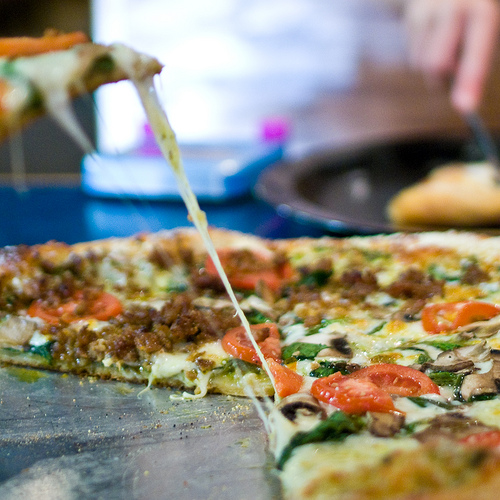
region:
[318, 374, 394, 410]
tomato on pizza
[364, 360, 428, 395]
red tomaoto as topping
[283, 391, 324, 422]
mushroom on the pizza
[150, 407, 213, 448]
pizza crumbs on pan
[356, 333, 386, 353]
cheese on the pizza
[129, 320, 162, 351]
hamburger on the pizza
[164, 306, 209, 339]
meat on pizza as topping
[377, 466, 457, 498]
crust of the pizza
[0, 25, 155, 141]
slice of the pizza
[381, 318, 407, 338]
yellow peppers on pizza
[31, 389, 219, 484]
The metal plate under the pizza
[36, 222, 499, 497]
Th pizza is on the platter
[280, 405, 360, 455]
The green vegetable on the pizza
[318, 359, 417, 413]
The tomato on the pizza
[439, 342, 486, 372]
The mushroom on the pizza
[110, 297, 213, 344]
The sausage on the pizza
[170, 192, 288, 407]
The cheese is the color white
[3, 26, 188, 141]
A slice of pizza in the air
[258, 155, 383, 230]
The plate is the color black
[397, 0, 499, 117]
The hand of the person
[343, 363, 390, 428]
There is a tomato that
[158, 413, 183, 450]
There is a silver plate that is here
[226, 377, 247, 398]
There is a light pizza crust that is here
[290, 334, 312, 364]
There is a piece of spinach that is here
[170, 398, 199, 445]
There are some spices that are on the pan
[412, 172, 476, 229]
There is a croissant that is visible here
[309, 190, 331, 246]
There is a plate that is visible here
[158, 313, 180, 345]
There is some spicy sausage here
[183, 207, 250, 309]
There is a great deal of cheese that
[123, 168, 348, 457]
Zander Zeke is the one who owns this photo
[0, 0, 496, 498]
Food is on the table.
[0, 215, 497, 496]
Pizza is on a platter.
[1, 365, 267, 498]
An empty space where the pizza used to be.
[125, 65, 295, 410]
A string of cheese hanging from the pizza.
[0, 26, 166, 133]
A slice of pizza is in the air.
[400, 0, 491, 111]
A person's hand is partially visible.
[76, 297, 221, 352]
Bacon is on the pizza.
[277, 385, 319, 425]
A mushroom is on the pizza.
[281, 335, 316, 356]
Green spinach is on the pizza.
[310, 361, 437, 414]
A slice of tomato is on the pizza.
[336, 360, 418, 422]
a piece of tomatoe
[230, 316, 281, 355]
a piece of tomatoe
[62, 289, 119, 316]
a piece of tomatoe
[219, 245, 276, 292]
a piece of tomatoe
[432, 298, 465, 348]
a piece of tomatoe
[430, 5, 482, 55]
that is a hand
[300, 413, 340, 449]
this is green vegatable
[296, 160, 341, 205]
that is a plate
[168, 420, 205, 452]
that is part of a plate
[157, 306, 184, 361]
that is a chunk of meat